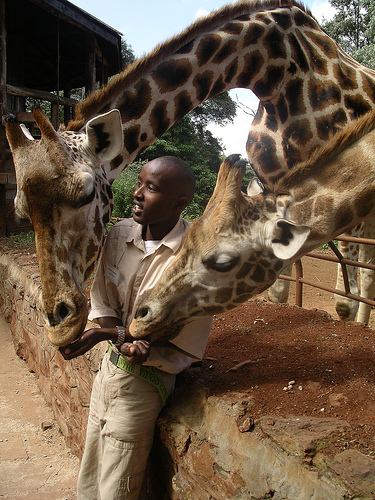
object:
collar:
[125, 215, 186, 255]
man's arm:
[96, 326, 131, 344]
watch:
[112, 325, 125, 346]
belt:
[105, 345, 170, 406]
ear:
[263, 215, 312, 262]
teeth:
[135, 204, 139, 208]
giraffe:
[1, 0, 374, 349]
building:
[8, 1, 121, 88]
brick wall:
[0, 244, 374, 497]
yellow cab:
[117, 147, 206, 235]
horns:
[205, 153, 248, 220]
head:
[133, 155, 196, 224]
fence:
[270, 236, 374, 324]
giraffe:
[130, 110, 374, 341]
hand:
[59, 327, 103, 361]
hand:
[119, 339, 150, 364]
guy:
[75, 154, 212, 499]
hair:
[164, 155, 197, 197]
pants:
[76, 353, 164, 500]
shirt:
[90, 220, 215, 374]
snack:
[58, 326, 79, 344]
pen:
[178, 149, 357, 307]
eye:
[211, 255, 240, 271]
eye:
[75, 187, 96, 211]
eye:
[14, 201, 30, 223]